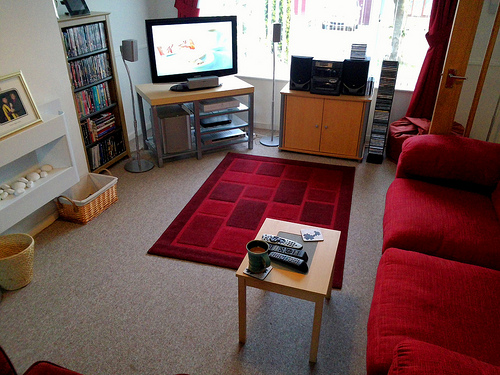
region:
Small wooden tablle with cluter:
[185, 185, 339, 360]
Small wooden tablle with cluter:
[275, 46, 373, 173]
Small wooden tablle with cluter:
[125, 74, 275, 166]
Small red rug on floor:
[155, 158, 369, 330]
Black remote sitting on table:
[270, 249, 305, 277]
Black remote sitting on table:
[265, 242, 304, 257]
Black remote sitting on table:
[264, 228, 302, 250]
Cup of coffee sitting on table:
[237, 233, 277, 290]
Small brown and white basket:
[43, 168, 119, 223]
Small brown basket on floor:
[1, 218, 43, 318]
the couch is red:
[427, 195, 457, 225]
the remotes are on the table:
[261, 228, 313, 272]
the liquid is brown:
[253, 245, 264, 255]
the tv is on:
[168, 35, 210, 52]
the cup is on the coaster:
[248, 247, 274, 276]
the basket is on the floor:
[78, 193, 106, 225]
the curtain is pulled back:
[420, 1, 437, 88]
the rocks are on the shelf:
[10, 163, 47, 193]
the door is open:
[436, 16, 457, 98]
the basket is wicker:
[78, 201, 102, 221]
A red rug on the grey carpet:
[174, 148, 359, 287]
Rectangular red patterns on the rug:
[275, 164, 337, 226]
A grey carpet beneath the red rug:
[99, 262, 226, 320]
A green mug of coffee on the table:
[243, 237, 272, 277]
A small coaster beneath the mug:
[242, 262, 273, 282]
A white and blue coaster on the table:
[301, 226, 326, 246]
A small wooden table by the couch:
[233, 212, 338, 370]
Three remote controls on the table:
[262, 229, 314, 271]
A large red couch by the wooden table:
[372, 141, 498, 368]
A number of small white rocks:
[11, 167, 56, 196]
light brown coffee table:
[229, 214, 341, 371]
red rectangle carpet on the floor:
[145, 147, 357, 292]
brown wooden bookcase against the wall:
[45, 7, 137, 175]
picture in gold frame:
[0, 70, 46, 142]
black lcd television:
[135, 12, 245, 95]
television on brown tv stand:
[134, 15, 257, 169]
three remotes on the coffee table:
[257, 230, 311, 275]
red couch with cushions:
[362, 129, 497, 367]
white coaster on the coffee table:
[298, 225, 323, 245]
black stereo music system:
[287, 40, 371, 100]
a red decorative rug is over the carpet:
[147, 145, 359, 310]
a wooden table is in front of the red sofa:
[234, 210, 346, 373]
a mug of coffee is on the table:
[246, 237, 277, 277]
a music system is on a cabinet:
[286, 51, 373, 96]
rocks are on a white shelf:
[2, 158, 68, 205]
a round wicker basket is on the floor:
[0, 229, 38, 296]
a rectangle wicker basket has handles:
[54, 168, 121, 224]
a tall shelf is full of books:
[57, 8, 129, 175]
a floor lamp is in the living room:
[117, 30, 154, 176]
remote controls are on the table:
[263, 226, 313, 277]